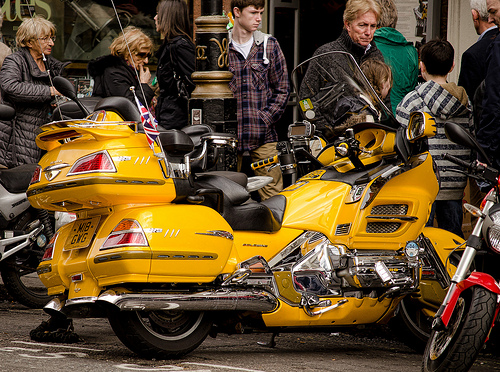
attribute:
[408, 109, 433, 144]
mirror — side view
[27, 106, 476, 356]
motorcycle — yellow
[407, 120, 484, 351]
motorcycle — red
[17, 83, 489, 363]
motorcycle — yellow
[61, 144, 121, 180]
light — off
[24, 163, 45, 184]
light — off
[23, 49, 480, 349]
bike — yellow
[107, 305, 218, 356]
tire — black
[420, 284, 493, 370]
tire — black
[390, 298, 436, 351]
tire — black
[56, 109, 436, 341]
motorcycle — yellow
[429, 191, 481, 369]
motorcycle — Red frame  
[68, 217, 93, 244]
letters — black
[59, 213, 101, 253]
plate — yellow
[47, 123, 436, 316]
motorcycle — large , yellow 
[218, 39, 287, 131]
jacket — plaid 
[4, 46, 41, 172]
jacket — black 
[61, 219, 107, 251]
license plate — yellow 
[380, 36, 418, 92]
jacket — green 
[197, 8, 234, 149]
light pole — black , gold 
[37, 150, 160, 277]
reartaillight —  yellow motorcycle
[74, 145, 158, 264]
reartaillight —  yellow motorcycle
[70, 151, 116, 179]
brake light — red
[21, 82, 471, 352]
bike — yellow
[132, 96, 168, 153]
flag — UK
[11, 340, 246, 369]
paint — white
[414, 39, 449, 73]
hair — black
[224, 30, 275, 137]
sweatshirt — plaid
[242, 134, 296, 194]
pants — khaki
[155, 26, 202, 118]
coat — black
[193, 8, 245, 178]
column — black, gold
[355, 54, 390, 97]
hair — braided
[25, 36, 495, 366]
motorcycle — yellow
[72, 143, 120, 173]
light — red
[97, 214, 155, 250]
light — red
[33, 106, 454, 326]
motorcycle — yellow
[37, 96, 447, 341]
motorcycle — yellow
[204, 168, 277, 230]
seat — leather, black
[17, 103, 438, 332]
motorcycle — yellow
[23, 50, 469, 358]
motorcycle — yellow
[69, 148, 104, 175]
light — red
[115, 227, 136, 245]
light — red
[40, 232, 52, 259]
light — red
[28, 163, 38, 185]
light — red